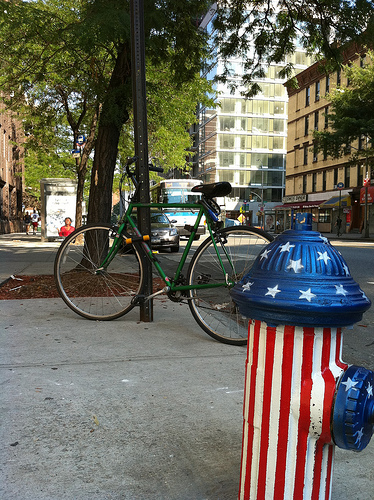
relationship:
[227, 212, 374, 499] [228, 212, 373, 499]
fire hydrant has american flag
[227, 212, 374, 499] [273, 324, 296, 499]
fire hydrant has stripe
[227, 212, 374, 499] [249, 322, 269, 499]
fire hydrant has stripe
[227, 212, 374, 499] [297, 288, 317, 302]
fire hydrant has star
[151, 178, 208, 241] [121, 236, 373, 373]
bus driving on street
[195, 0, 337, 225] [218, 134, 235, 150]
building has window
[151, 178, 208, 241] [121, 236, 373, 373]
bus coming down street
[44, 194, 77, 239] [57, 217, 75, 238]
sign with woman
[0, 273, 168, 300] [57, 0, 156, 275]
mulch around tree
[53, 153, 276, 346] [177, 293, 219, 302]
bike has kickstand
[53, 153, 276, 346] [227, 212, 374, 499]
bike behind fire hydrant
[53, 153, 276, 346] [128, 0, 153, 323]
bike near pole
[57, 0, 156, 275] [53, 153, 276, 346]
tree behind bike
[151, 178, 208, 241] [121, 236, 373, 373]
bus on top of street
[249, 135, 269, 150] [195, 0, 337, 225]
window covering building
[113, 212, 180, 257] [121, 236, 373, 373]
car parked on street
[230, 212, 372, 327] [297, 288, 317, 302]
top has star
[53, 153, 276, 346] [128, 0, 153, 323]
bike leaning against pole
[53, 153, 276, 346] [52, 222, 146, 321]
bike has tire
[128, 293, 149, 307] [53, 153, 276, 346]
pedal on side of bike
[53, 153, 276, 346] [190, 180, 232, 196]
bike has seat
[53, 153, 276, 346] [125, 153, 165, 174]
bike has handlebars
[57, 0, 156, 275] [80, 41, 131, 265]
tree has trunk